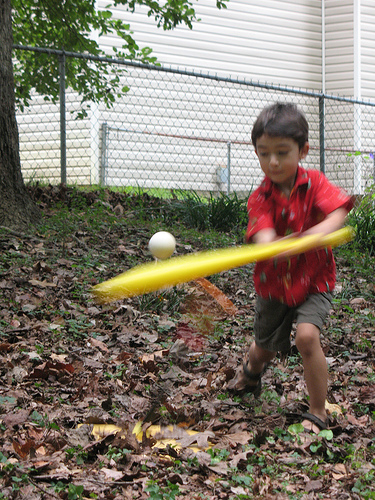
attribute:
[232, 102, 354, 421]
boy — playing, playing baseball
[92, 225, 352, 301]
bat — yellow, plastic, in motion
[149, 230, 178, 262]
ball — round, white in color, toy, plastic, in midair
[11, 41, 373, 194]
house — metal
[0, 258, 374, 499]
leaves — dead, yellow, brown, dry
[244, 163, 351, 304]
shirt — button down, patterned, red patterned, red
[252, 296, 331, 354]
shorts — cargo shorts, dark grey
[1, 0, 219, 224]
tree — green, green leafed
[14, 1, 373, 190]
home — sided, here, white